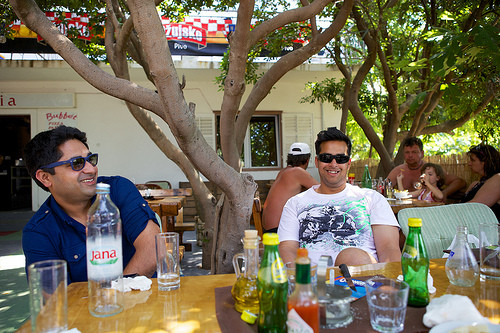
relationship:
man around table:
[22, 125, 169, 295] [15, 257, 500, 333]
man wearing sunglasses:
[22, 125, 169, 295] [39, 153, 99, 172]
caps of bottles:
[259, 214, 429, 254] [253, 214, 419, 299]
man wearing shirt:
[30, 139, 127, 287] [19, 203, 182, 299]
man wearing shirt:
[261, 118, 377, 282] [298, 175, 362, 265]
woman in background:
[456, 144, 486, 196] [18, 6, 491, 297]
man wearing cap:
[264, 143, 309, 235] [288, 142, 312, 155]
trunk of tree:
[200, 157, 269, 277] [37, 8, 319, 249]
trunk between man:
[200, 157, 269, 277] [22, 125, 169, 295]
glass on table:
[30, 262, 84, 332] [56, 245, 491, 329]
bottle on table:
[290, 255, 318, 330] [56, 245, 491, 329]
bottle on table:
[87, 188, 127, 296] [56, 245, 491, 329]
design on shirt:
[307, 207, 356, 251] [298, 175, 362, 265]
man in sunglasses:
[30, 139, 127, 287] [43, 153, 99, 179]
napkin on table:
[434, 289, 488, 331] [56, 245, 491, 329]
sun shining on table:
[162, 320, 199, 332] [56, 245, 491, 329]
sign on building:
[6, 13, 319, 69] [3, 34, 398, 211]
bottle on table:
[217, 227, 284, 301] [56, 245, 491, 329]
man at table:
[22, 125, 169, 295] [56, 245, 491, 329]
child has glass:
[414, 153, 449, 205] [408, 174, 431, 183]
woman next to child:
[456, 144, 486, 196] [414, 153, 449, 205]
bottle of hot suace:
[290, 255, 318, 330] [291, 306, 318, 331]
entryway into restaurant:
[0, 111, 30, 214] [1, 46, 373, 214]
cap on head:
[290, 140, 318, 162] [290, 144, 313, 169]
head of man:
[290, 144, 313, 169] [264, 143, 309, 235]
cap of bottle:
[408, 216, 421, 231] [407, 214, 432, 304]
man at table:
[30, 139, 127, 287] [56, 245, 491, 329]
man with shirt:
[30, 139, 127, 287] [19, 203, 182, 299]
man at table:
[261, 118, 377, 282] [56, 245, 491, 329]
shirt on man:
[298, 175, 362, 265] [261, 118, 377, 282]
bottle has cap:
[407, 214, 432, 304] [408, 216, 421, 231]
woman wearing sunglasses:
[456, 144, 486, 196] [472, 148, 498, 164]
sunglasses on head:
[472, 148, 498, 164] [471, 144, 498, 177]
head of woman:
[471, 144, 498, 177] [456, 144, 486, 196]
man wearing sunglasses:
[30, 139, 127, 287] [43, 153, 99, 179]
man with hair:
[30, 139, 127, 287] [34, 127, 85, 162]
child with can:
[395, 163, 444, 205] [418, 170, 429, 187]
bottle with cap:
[407, 214, 432, 304] [407, 217, 423, 227]